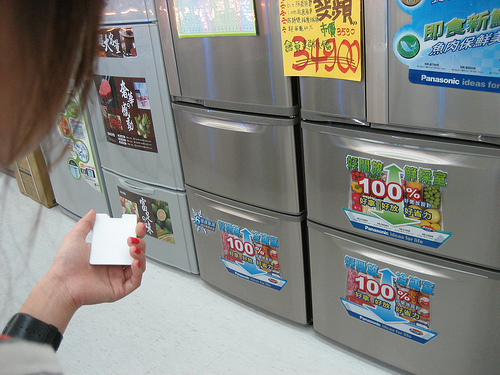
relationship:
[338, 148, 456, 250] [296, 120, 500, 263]
sign on door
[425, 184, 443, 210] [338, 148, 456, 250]
grapes in picture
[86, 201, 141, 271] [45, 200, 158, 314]
phone in hand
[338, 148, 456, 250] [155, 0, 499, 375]
sign on appliance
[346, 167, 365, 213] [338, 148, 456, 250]
tomatoes are on advertisment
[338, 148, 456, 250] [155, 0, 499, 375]
sign on shelf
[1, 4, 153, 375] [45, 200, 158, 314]
girl has hand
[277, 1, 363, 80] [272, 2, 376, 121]
display in box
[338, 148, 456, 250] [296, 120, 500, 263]
display in oven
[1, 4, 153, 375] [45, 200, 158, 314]
person has hand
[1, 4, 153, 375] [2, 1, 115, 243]
girl has hair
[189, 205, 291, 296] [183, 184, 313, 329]
sticker to machine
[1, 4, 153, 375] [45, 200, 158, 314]
woman has hand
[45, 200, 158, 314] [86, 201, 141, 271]
hand holding phone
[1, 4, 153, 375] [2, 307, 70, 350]
woman wearing band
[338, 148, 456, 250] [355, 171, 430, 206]
display written 100%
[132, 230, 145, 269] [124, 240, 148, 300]
nail polish on fingers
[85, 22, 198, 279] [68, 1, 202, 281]
door on refridgerator